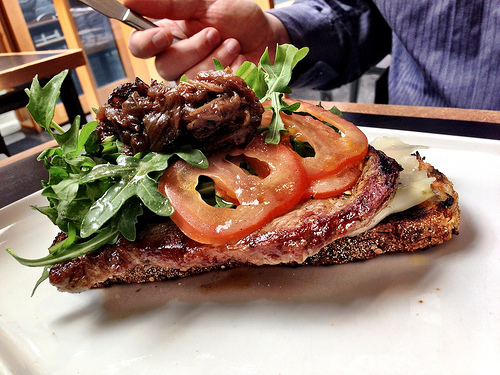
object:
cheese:
[348, 135, 437, 238]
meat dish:
[3, 41, 461, 297]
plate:
[0, 125, 500, 375]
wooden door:
[0, 0, 154, 132]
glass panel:
[66, 0, 127, 90]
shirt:
[264, 0, 500, 112]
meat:
[88, 256, 298, 288]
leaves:
[211, 56, 226, 71]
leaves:
[108, 195, 143, 243]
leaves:
[36, 146, 62, 162]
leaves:
[30, 265, 53, 298]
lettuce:
[6, 221, 122, 268]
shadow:
[47, 203, 481, 334]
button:
[311, 4, 324, 12]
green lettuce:
[77, 144, 210, 240]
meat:
[301, 149, 463, 280]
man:
[119, 0, 500, 113]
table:
[0, 47, 89, 158]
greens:
[23, 67, 70, 137]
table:
[0, 97, 500, 209]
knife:
[76, 0, 183, 46]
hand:
[122, 0, 282, 86]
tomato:
[243, 91, 371, 184]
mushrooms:
[139, 87, 181, 153]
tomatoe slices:
[249, 158, 365, 202]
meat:
[95, 76, 260, 160]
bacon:
[50, 144, 403, 295]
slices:
[157, 136, 309, 248]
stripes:
[477, 3, 499, 110]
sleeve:
[264, 0, 392, 95]